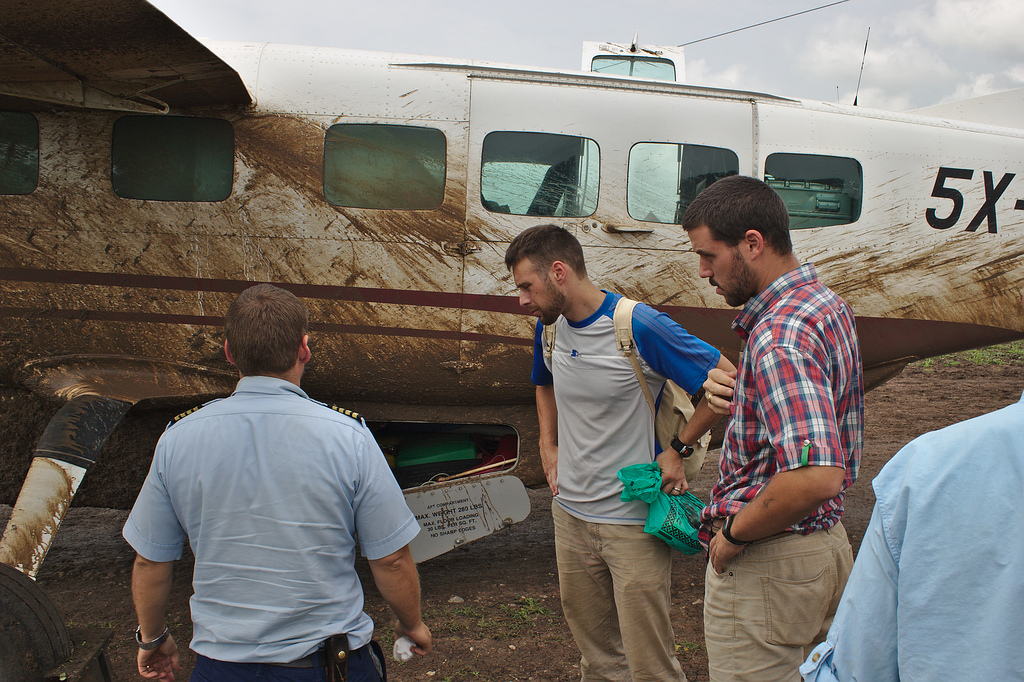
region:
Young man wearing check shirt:
[674, 172, 868, 679]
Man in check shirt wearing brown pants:
[675, 170, 868, 679]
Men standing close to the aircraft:
[0, 7, 1022, 678]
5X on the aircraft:
[918, 163, 1016, 239]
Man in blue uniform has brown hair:
[117, 277, 435, 679]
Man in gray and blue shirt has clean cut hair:
[497, 222, 747, 679]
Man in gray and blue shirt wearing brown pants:
[497, 222, 744, 679]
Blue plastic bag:
[611, 459, 710, 562]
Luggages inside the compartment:
[368, 426, 514, 485]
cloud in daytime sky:
[161, 1, 1021, 131]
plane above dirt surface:
[0, 1, 1022, 673]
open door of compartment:
[375, 419, 530, 559]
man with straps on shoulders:
[502, 225, 731, 679]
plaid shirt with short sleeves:
[699, 270, 861, 542]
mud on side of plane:
[0, 119, 1016, 408]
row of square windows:
[2, 110, 860, 232]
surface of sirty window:
[322, 125, 444, 209]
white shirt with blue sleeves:
[531, 296, 727, 531]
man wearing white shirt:
[468, 215, 693, 677]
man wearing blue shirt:
[109, 263, 465, 679]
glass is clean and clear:
[622, 138, 740, 221]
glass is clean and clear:
[113, 116, 240, 205]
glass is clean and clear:
[592, 55, 673, 81]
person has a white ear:
[552, 258, 569, 284]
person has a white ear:
[739, 223, 765, 258]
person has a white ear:
[298, 331, 309, 361]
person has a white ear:
[222, 337, 239, 367]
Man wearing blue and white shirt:
[484, 221, 731, 671]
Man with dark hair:
[477, 215, 747, 674]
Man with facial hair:
[482, 220, 758, 679]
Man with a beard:
[477, 236, 724, 677]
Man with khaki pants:
[482, 220, 736, 663]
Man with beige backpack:
[458, 224, 725, 657]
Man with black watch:
[483, 221, 749, 668]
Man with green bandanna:
[457, 230, 730, 658]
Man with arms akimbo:
[480, 222, 738, 652]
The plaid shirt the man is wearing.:
[685, 281, 859, 539]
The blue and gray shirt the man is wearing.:
[523, 296, 711, 522]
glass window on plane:
[117, 113, 234, 200]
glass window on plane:
[321, 123, 449, 209]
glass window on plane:
[483, 132, 601, 216]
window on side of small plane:
[2, 103, 41, 195]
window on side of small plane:
[114, 115, 233, 200]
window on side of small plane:
[324, 120, 445, 210]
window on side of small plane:
[482, 133, 603, 218]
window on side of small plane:
[629, 142, 743, 227]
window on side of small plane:
[765, 152, 860, 225]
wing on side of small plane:
[0, 3, 258, 120]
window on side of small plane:
[595, 59, 677, 80]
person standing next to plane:
[119, 281, 435, 678]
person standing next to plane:
[504, 223, 738, 678]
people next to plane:
[113, 138, 857, 518]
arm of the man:
[321, 397, 477, 648]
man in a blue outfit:
[70, 241, 459, 631]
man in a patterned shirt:
[568, 143, 946, 600]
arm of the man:
[628, 432, 863, 626]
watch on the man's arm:
[688, 497, 787, 577]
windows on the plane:
[223, 120, 726, 270]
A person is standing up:
[654, 160, 855, 679]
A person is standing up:
[471, 198, 753, 677]